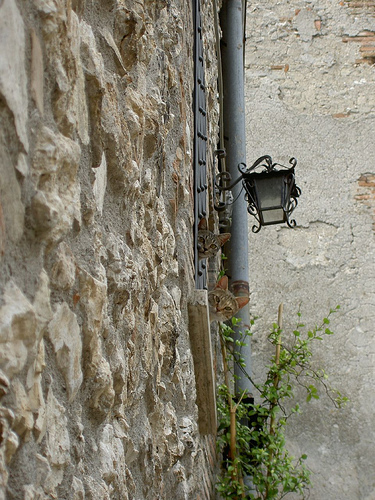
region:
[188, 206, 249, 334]
Two cats looking out a window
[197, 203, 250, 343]
Two cats sticking there heads out of a window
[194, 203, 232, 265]
A cat looking out a window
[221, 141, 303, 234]
A lamp next to a window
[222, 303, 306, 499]
A plant next to a building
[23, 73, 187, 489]
A rocky wall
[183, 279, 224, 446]
A window sill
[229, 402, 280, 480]
Leaves on a plant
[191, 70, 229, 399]
A window on a building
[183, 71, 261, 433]
A window with two cats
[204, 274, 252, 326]
Cat leaning over a ledge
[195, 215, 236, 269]
Cat peering out a window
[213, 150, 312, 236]
Outdoor light attached to wall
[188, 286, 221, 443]
Ledge on the window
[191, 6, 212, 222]
Steel bars on a window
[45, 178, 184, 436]
Wall made of stone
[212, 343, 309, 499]
Plant growing in the corner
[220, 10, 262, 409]
Utility pipe mounted into corner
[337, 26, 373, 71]
Exposed bricks in the wall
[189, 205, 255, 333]
A couple of cats looking out the window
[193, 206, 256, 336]
two cats looking out the window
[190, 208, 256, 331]
two furry domesticated felines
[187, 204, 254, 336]
two furry mammal pets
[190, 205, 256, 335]
two brown and grey cats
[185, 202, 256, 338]
brown and grey felines with large ears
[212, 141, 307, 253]
stylized decorative black lamp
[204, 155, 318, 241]
black hanging wall lamp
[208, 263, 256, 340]
cat with large pink ears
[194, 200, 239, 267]
small cat with large ears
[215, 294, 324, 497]
plant growing on side of house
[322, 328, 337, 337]
green leaf on trellis plant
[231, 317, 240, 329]
green leaf on trellis plant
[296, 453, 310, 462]
green leaf on trellis plant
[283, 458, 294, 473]
green leaf on trellis plant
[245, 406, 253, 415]
green leaf on trellis plant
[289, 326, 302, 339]
green leaf on trellis plant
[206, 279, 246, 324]
cat of head sticking out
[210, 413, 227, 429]
green leaf on trellis plant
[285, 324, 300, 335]
green leaf on trellis plant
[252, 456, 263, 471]
green leaf on trellis plant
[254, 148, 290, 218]
this is a lump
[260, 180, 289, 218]
the lump is not lightening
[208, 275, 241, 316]
this is a cat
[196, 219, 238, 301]
they are two cats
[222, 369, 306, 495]
this is a tree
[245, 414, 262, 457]
the leaves are green in color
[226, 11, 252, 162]
this is a pole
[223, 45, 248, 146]
the pole is metallic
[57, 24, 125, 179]
this is the wall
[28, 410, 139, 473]
the wall is made of stones